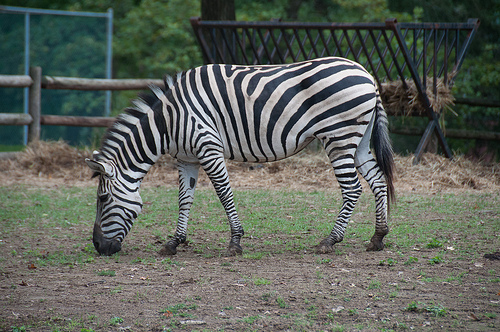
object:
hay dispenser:
[186, 8, 476, 162]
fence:
[1, 64, 109, 139]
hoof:
[225, 231, 247, 256]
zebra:
[84, 53, 393, 258]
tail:
[374, 80, 401, 206]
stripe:
[229, 63, 280, 161]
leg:
[200, 139, 248, 257]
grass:
[0, 183, 499, 258]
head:
[86, 155, 142, 257]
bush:
[113, 2, 188, 80]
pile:
[0, 133, 90, 178]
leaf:
[444, 242, 457, 253]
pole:
[41, 72, 159, 92]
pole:
[32, 110, 130, 129]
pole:
[0, 69, 39, 91]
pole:
[0, 103, 41, 128]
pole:
[25, 59, 49, 156]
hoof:
[154, 235, 179, 257]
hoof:
[306, 230, 341, 258]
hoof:
[362, 234, 386, 251]